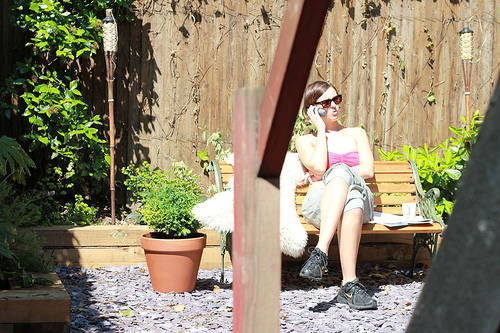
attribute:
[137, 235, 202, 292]
flower pot — brown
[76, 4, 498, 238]
fence — brown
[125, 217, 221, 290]
pot — brown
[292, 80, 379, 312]
she — sitting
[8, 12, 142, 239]
plants — green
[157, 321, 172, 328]
rock — grey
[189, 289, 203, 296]
rock — grey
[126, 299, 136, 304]
rock — grey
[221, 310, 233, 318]
rock — grey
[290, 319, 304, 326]
rock — grey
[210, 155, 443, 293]
bench — brown, wooden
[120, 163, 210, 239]
plant — green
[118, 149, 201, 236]
plant — green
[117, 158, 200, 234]
bush — green